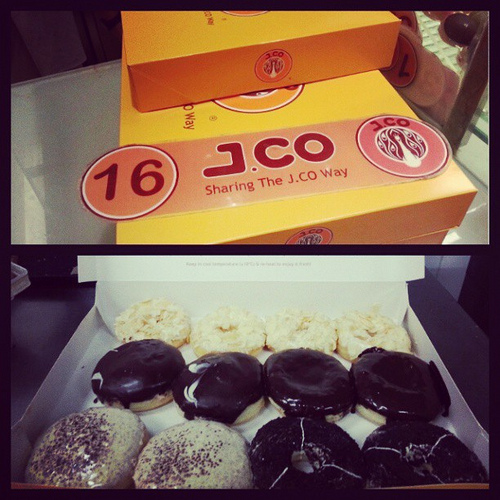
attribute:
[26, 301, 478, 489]
donuts — iced, assorted, different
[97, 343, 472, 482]
donuts — chocolate, black iced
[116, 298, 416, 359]
donuts — white iced, white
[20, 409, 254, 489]
donuts — white iced, holeless, white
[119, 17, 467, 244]
box — closed, yellow, cardboard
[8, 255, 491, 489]
box — open, white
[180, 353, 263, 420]
chocolate — dripping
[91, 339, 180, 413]
donut — chocolate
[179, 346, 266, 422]
donut — chocolate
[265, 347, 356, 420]
donut — chocolate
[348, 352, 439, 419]
donut — chocolate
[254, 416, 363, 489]
donut — chocolate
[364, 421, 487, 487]
donut — chocolate